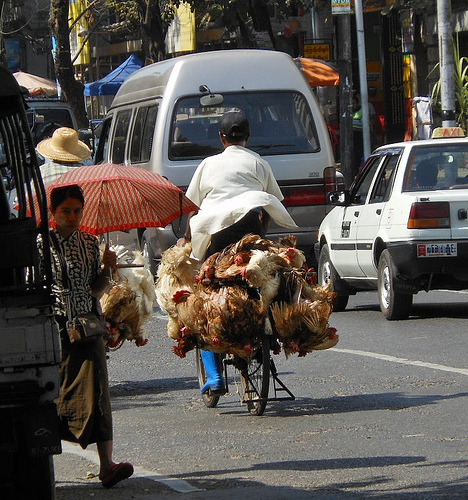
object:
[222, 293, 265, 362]
chicken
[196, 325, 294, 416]
bike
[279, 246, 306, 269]
chicken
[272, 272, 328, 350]
chicken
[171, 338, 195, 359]
chicken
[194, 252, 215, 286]
chicken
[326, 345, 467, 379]
line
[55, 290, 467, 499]
road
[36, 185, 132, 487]
woman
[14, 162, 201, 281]
umbrella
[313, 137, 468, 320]
car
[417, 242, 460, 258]
sticker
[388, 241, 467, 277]
bumper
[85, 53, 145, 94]
umbrella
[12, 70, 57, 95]
umbrella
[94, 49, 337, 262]
van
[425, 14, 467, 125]
plant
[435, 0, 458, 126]
pole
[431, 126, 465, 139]
taxi sign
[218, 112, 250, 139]
hat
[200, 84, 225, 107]
mirror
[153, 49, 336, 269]
back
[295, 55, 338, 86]
umbrella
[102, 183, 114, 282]
handle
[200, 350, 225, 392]
boot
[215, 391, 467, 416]
shadow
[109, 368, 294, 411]
shadow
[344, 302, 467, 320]
shadow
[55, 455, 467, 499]
shadow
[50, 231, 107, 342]
purse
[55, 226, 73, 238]
neck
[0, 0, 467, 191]
sidewalk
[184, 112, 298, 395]
man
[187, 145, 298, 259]
shirt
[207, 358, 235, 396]
pedal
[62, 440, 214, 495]
line